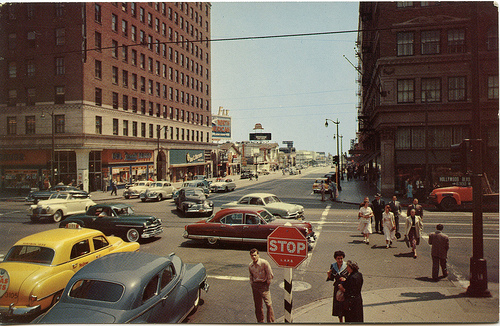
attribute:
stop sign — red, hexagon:
[266, 224, 311, 269]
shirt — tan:
[247, 258, 274, 285]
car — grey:
[27, 250, 209, 325]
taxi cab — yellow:
[1, 221, 141, 319]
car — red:
[181, 206, 317, 245]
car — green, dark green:
[58, 202, 164, 243]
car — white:
[219, 190, 305, 219]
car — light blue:
[180, 173, 213, 189]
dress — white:
[382, 211, 399, 242]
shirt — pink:
[319, 183, 326, 193]